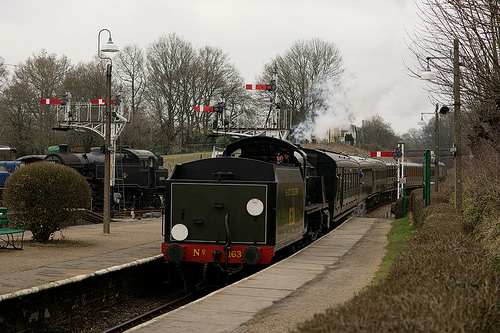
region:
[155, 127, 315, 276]
a black and red train car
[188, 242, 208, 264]
yellow writing on the train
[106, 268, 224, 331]
a metal train track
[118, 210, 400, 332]
a gray cement sidewalk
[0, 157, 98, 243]
a trimmed bush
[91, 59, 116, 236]
a wooden post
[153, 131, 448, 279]
a train on the tracks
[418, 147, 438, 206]
a green post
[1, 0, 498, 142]
a gray overcast sky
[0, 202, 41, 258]
a green bench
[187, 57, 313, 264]
a train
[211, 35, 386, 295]
a train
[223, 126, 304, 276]
a train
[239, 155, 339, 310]
a train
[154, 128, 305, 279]
a small black train engine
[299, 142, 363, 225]
a black train passenger car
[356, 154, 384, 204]
a black train passenger car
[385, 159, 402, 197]
a black train passenger car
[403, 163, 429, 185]
a black train passenger car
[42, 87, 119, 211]
a railroad traffic signal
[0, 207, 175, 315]
a train boarding platform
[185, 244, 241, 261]
printed train No 163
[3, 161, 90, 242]
a large green bush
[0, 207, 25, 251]
a green park bench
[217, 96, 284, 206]
a train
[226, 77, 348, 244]
a train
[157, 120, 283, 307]
a train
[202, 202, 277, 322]
a train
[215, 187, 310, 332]
a train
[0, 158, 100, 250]
a bush on the sidewalk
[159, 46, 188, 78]
the branches of a tree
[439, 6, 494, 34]
the branches of a tree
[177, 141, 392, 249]
a black train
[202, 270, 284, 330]
a cement sidewalk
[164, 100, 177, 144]
the trunk of a tree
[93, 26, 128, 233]
a light pole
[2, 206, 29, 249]
a bench on the sidewalk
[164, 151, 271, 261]
the back of a train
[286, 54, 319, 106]
the branches of a tree